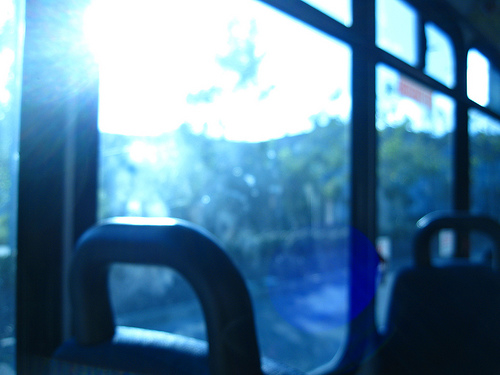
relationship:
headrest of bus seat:
[68, 214, 263, 366] [48, 216, 310, 374]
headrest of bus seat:
[409, 209, 499, 271] [381, 209, 499, 373]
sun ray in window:
[34, 0, 226, 136] [128, 17, 344, 353]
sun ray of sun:
[34, 0, 226, 136] [148, 5, 265, 102]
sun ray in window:
[107, 6, 312, 119] [101, 0, 491, 336]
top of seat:
[85, 216, 186, 243] [36, 187, 263, 371]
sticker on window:
[396, 64, 433, 112] [91, 11, 471, 342]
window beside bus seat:
[98, 0, 350, 368] [48, 216, 310, 374]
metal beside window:
[352, 3, 376, 360] [375, 64, 456, 330]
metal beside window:
[352, 3, 376, 360] [98, 0, 350, 368]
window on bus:
[467, 46, 499, 117] [0, 3, 499, 370]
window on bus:
[421, 18, 456, 92] [0, 3, 499, 370]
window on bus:
[370, 0, 424, 70] [0, 3, 499, 370]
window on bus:
[255, 0, 355, 33] [0, 3, 499, 370]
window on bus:
[368, 47, 463, 350] [0, 3, 499, 370]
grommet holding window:
[330, 337, 352, 369] [98, 0, 350, 368]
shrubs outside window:
[99, 115, 499, 312] [28, 2, 387, 367]